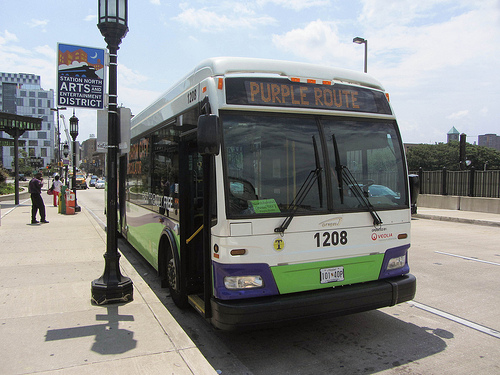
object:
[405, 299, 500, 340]
line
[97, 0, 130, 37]
lamp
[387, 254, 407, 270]
headlight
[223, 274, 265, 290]
headlight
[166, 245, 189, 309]
wheel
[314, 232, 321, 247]
number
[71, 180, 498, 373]
street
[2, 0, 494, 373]
city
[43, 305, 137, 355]
shadow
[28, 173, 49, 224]
man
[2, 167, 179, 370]
side walk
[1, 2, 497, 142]
sky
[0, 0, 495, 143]
clouds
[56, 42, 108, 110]
sign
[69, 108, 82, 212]
pole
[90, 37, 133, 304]
lamp post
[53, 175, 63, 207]
lady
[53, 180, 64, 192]
blouse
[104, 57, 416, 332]
bus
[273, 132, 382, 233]
wiper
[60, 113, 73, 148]
crane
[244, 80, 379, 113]
sign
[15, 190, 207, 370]
ground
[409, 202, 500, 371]
road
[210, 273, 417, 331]
bumper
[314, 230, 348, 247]
1208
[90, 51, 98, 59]
moon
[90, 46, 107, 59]
corner